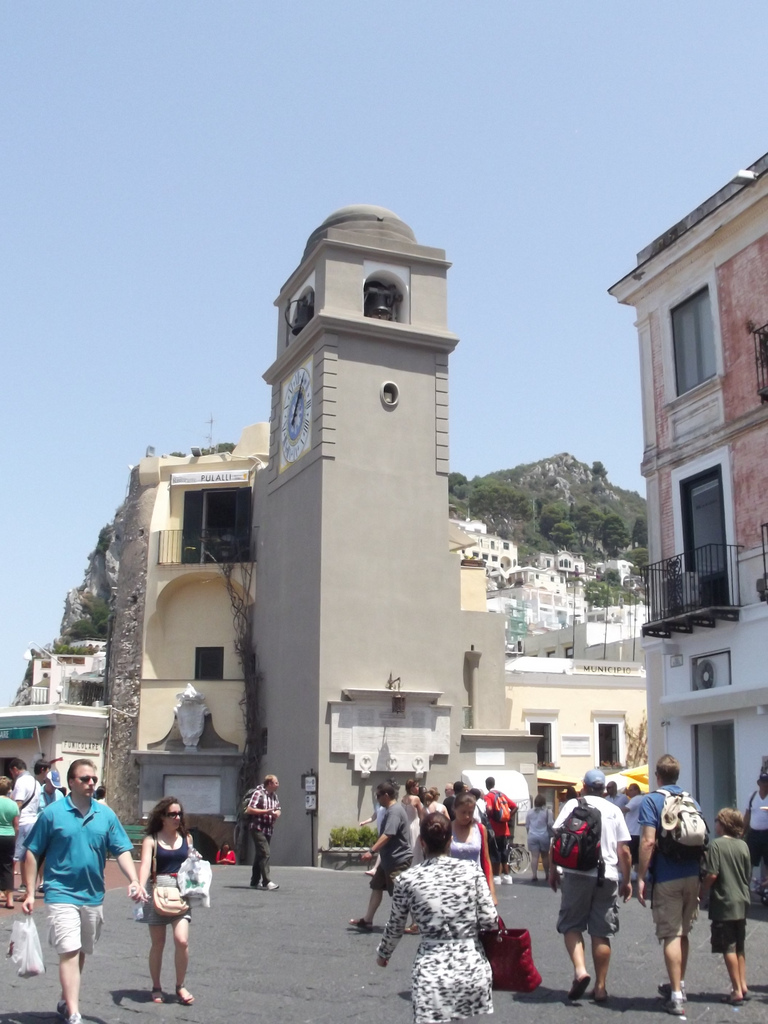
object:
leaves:
[508, 517, 538, 541]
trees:
[448, 451, 646, 552]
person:
[376, 811, 543, 1022]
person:
[139, 797, 213, 1007]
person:
[6, 758, 144, 1023]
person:
[549, 767, 632, 1003]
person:
[637, 755, 711, 1024]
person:
[699, 807, 753, 1007]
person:
[349, 781, 415, 931]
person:
[246, 775, 282, 889]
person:
[451, 792, 499, 905]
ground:
[0, 863, 768, 1021]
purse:
[479, 915, 545, 994]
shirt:
[22, 792, 131, 905]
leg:
[590, 881, 622, 1001]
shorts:
[651, 874, 698, 946]